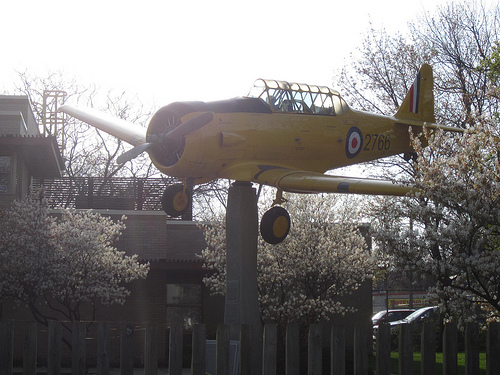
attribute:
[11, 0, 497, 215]
sky — has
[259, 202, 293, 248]
wheel — on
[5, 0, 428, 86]
clouds — in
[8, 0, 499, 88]
sky — with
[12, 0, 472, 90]
clouds — are in 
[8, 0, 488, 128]
sky — has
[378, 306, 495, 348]
car — motionless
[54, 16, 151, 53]
clouds — high in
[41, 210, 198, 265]
wall — large, stone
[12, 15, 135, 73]
clouds — are in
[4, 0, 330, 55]
sky — has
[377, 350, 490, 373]
lawn — green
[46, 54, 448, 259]
airplane — attached to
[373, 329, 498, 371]
grass — green, lushy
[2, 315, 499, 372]
fence — below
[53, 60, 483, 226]
plane — small, yellow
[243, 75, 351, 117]
frame — curved, metal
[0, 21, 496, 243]
sky — with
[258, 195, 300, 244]
landing gear — attached to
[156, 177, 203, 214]
landing gear — on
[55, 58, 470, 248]
yellow airplane — has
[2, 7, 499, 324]
trees — round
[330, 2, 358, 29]
white clouds — with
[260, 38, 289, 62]
white clouds — with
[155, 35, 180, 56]
white clouds — with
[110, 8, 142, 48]
white clouds — with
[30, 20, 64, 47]
white clouds — with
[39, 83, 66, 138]
metal frame — big, steady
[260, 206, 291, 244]
wheel — black, yellow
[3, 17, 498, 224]
sky — with, clear, white, cloudless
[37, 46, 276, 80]
clouds — white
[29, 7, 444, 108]
sky — blue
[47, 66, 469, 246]
airplane — with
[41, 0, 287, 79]
light — bright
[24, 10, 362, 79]
clouds — in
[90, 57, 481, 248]
plane — has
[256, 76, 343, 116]
cockpit — ontop